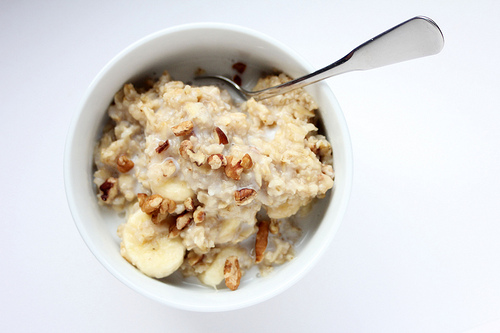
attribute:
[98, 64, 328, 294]
oatmeal — cooked, creamy, clump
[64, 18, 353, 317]
bowl — white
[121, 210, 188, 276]
banana — sliced, small, circle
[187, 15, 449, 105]
spoon — to eat, sticking out, silver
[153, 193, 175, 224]
walnut — crushed, brown, chopped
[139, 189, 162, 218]
walnut — crushed, brown, chopped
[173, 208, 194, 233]
walnut — crushed, brown, chopped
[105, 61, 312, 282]
milk — almond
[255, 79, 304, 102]
reflection — smallest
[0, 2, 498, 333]
table — white